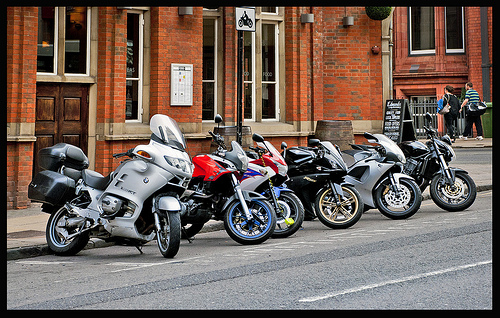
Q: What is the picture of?
A: It is a picture of some motorcycles parked by the roadside.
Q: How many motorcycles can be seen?
A: Six.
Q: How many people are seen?
A: Two.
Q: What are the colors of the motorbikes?
A: Two of them are red, two are white and the remaining two are black.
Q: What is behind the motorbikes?
A: A building.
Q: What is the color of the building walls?
A: Brick-red.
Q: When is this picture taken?
A: Day-time.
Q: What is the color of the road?
A: Grey.